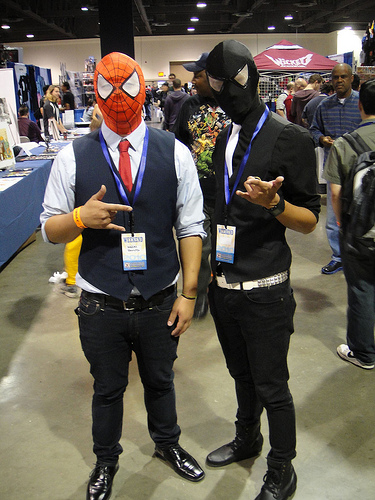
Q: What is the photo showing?
A: It is showing a sidewalk.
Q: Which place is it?
A: It is a sidewalk.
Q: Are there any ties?
A: Yes, there is a tie.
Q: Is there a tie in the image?
A: Yes, there is a tie.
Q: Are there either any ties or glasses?
A: Yes, there is a tie.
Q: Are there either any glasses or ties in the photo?
A: Yes, there is a tie.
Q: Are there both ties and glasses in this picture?
A: No, there is a tie but no glasses.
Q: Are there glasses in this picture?
A: No, there are no glasses.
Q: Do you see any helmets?
A: No, there are no helmets.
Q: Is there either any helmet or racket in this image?
A: No, there are no helmets or rackets.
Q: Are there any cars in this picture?
A: No, there are no cars.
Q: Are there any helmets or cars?
A: No, there are no cars or helmets.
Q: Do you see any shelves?
A: No, there are no shelves.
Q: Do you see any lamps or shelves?
A: No, there are no shelves or lamps.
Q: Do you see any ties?
A: Yes, there is a tie.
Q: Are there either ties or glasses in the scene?
A: Yes, there is a tie.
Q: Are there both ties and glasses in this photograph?
A: No, there is a tie but no glasses.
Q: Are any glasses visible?
A: No, there are no glasses.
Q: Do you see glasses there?
A: No, there are no glasses.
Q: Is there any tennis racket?
A: No, there are no rackets.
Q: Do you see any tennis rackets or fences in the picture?
A: No, there are no tennis rackets or fences.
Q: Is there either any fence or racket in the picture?
A: No, there are no rackets or fences.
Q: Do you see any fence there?
A: No, there are no fences.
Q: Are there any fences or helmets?
A: No, there are no fences or helmets.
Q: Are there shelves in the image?
A: No, there are no shelves.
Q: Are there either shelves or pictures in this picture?
A: No, there are no shelves or pictures.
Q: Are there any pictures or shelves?
A: No, there are no shelves or pictures.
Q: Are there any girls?
A: No, there are no girls.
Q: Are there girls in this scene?
A: No, there are no girls.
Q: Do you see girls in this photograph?
A: No, there are no girls.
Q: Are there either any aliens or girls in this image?
A: No, there are no girls or aliens.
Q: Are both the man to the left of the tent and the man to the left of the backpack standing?
A: Yes, both the man and the man are standing.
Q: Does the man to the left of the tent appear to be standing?
A: Yes, the man is standing.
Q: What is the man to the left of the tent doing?
A: The man is standing.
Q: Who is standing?
A: The man is standing.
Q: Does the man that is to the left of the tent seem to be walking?
A: No, the man is standing.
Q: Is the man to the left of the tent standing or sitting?
A: The man is standing.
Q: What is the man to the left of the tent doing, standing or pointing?
A: The man is standing.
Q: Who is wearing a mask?
A: The man is wearing a mask.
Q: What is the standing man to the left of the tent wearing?
A: The man is wearing a mask.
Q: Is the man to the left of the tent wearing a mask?
A: Yes, the man is wearing a mask.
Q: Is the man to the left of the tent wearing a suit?
A: No, the man is wearing a mask.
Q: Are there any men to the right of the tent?
A: No, the man is to the left of the tent.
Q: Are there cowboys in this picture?
A: No, there are no cowboys.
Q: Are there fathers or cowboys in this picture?
A: No, there are no cowboys or fathers.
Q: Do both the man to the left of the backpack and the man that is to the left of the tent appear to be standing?
A: Yes, both the man and the man are standing.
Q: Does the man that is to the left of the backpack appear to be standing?
A: Yes, the man is standing.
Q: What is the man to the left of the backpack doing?
A: The man is standing.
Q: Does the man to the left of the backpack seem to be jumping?
A: No, the man is standing.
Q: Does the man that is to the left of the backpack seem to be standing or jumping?
A: The man is standing.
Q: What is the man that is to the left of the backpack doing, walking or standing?
A: The man is standing.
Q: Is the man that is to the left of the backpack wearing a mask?
A: Yes, the man is wearing a mask.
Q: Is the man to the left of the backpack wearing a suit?
A: No, the man is wearing a mask.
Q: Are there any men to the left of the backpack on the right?
A: Yes, there is a man to the left of the backpack.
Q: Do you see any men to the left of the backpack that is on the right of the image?
A: Yes, there is a man to the left of the backpack.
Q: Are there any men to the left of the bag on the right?
A: Yes, there is a man to the left of the backpack.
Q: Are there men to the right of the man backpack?
A: No, the man is to the left of the backpack.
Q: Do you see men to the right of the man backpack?
A: No, the man is to the left of the backpack.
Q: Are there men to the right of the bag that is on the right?
A: No, the man is to the left of the backpack.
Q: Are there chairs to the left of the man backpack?
A: No, there is a man to the left of the backpack.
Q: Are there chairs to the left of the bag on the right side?
A: No, there is a man to the left of the backpack.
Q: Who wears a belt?
A: The man wears a belt.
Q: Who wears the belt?
A: The man wears a belt.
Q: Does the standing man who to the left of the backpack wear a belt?
A: Yes, the man wears a belt.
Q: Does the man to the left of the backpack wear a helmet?
A: No, the man wears a belt.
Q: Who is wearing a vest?
A: The man is wearing a vest.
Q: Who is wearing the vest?
A: The man is wearing a vest.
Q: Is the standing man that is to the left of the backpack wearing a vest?
A: Yes, the man is wearing a vest.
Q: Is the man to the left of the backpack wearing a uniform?
A: No, the man is wearing a vest.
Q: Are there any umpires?
A: No, there are no umpires.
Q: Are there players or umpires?
A: No, there are no umpires or players.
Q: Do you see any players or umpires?
A: No, there are no umpires or players.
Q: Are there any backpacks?
A: Yes, there is a backpack.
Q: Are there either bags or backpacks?
A: Yes, there is a backpack.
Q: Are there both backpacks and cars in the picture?
A: No, there is a backpack but no cars.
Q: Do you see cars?
A: No, there are no cars.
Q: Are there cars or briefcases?
A: No, there are no cars or briefcases.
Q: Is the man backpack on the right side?
A: Yes, the backpack is on the right of the image.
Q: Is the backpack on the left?
A: No, the backpack is on the right of the image.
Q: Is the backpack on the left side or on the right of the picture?
A: The backpack is on the right of the image.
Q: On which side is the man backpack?
A: The backpack is on the right of the image.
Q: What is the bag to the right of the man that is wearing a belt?
A: The bag is a backpack.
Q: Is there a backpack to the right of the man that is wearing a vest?
A: Yes, there is a backpack to the right of the man.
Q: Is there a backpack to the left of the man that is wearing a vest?
A: No, the backpack is to the right of the man.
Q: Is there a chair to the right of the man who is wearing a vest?
A: No, there is a backpack to the right of the man.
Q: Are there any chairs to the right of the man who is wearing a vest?
A: No, there is a backpack to the right of the man.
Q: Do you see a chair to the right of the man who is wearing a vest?
A: No, there is a backpack to the right of the man.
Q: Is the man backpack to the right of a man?
A: Yes, the backpack is to the right of a man.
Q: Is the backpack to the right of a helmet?
A: No, the backpack is to the right of a man.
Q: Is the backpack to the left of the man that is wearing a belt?
A: No, the backpack is to the right of the man.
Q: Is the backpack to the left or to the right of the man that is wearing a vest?
A: The backpack is to the right of the man.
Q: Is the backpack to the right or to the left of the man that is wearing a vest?
A: The backpack is to the right of the man.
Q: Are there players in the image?
A: No, there are no players.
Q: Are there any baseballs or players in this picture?
A: No, there are no players or baseballs.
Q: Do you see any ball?
A: No, there are no balls.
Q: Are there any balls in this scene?
A: No, there are no balls.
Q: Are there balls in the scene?
A: No, there are no balls.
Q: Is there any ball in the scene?
A: No, there are no balls.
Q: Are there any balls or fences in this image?
A: No, there are no balls or fences.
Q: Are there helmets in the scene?
A: No, there are no helmets.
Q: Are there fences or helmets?
A: No, there are no helmets or fences.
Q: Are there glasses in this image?
A: No, there are no glasses.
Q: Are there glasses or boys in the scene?
A: No, there are no glasses or boys.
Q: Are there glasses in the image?
A: No, there are no glasses.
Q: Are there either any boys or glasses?
A: No, there are no glasses or boys.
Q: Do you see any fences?
A: No, there are no fences.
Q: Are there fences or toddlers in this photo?
A: No, there are no fences or toddlers.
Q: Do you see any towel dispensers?
A: No, there are no towel dispensers.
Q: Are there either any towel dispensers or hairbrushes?
A: No, there are no towel dispensers or hairbrushes.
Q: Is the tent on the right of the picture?
A: Yes, the tent is on the right of the image.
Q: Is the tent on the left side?
A: No, the tent is on the right of the image.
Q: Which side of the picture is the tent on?
A: The tent is on the right of the image.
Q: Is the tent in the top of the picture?
A: Yes, the tent is in the top of the image.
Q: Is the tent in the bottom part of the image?
A: No, the tent is in the top of the image.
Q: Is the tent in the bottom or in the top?
A: The tent is in the top of the image.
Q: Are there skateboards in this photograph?
A: No, there are no skateboards.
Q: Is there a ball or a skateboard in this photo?
A: No, there are no skateboards or balls.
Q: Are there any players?
A: No, there are no players.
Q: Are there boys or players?
A: No, there are no players or boys.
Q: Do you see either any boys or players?
A: No, there are no players or boys.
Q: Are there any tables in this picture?
A: Yes, there is a table.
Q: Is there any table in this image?
A: Yes, there is a table.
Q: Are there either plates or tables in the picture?
A: Yes, there is a table.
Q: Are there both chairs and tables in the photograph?
A: No, there is a table but no chairs.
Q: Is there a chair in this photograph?
A: No, there are no chairs.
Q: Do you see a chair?
A: No, there are no chairs.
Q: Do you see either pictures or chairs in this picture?
A: No, there are no chairs or pictures.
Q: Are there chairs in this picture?
A: No, there are no chairs.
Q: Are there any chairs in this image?
A: No, there are no chairs.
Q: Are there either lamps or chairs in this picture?
A: No, there are no chairs or lamps.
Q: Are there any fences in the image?
A: No, there are no fences.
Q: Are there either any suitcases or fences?
A: No, there are no fences or suitcases.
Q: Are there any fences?
A: No, there are no fences.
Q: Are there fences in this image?
A: No, there are no fences.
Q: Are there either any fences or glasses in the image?
A: No, there are no fences or glasses.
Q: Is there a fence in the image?
A: No, there are no fences.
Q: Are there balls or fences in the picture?
A: No, there are no fences or balls.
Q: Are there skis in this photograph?
A: No, there are no skis.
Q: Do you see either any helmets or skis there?
A: No, there are no skis or helmets.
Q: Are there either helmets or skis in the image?
A: No, there are no skis or helmets.